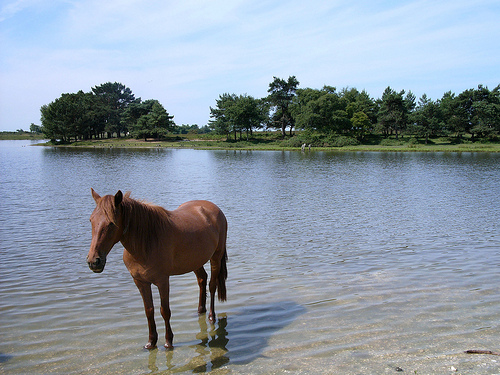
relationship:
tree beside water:
[207, 105, 239, 141] [0, 138, 500, 373]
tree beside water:
[127, 111, 169, 141] [0, 138, 500, 373]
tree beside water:
[29, 97, 76, 146] [0, 138, 500, 373]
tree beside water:
[267, 74, 300, 137] [0, 138, 500, 373]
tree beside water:
[350, 112, 375, 146] [0, 138, 500, 373]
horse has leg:
[88, 188, 229, 350] [154, 276, 175, 348]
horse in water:
[88, 188, 229, 350] [0, 138, 500, 373]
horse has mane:
[88, 188, 229, 350] [100, 193, 167, 229]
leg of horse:
[154, 276, 175, 348] [88, 188, 229, 350]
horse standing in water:
[88, 188, 229, 350] [0, 138, 500, 373]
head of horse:
[87, 189, 126, 273] [88, 188, 229, 350]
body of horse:
[123, 199, 228, 278] [88, 188, 229, 350]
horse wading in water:
[88, 188, 229, 350] [0, 138, 500, 373]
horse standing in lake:
[88, 188, 229, 350] [0, 138, 500, 373]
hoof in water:
[210, 312, 215, 319] [0, 138, 500, 373]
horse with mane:
[88, 188, 229, 350] [100, 193, 167, 229]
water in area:
[0, 138, 500, 373] [2, 82, 498, 374]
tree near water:
[29, 97, 76, 146] [0, 138, 500, 373]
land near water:
[32, 120, 500, 155] [0, 138, 500, 373]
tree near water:
[350, 112, 375, 146] [0, 138, 500, 373]